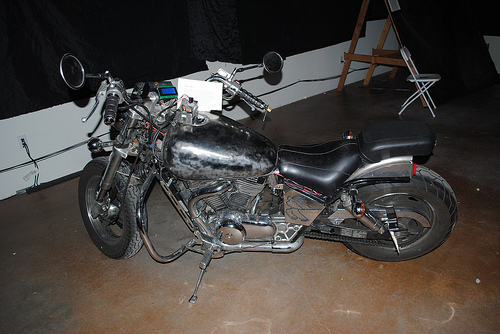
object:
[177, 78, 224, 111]
paper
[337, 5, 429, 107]
wooden support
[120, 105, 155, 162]
wires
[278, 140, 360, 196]
seat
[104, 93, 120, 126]
handle bar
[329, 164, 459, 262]
back wheel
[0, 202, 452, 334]
ground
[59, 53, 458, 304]
bike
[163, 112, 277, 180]
fuel tank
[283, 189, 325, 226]
brown panel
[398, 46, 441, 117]
chair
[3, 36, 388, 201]
panel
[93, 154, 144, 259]
dust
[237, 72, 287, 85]
shadow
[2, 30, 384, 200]
wood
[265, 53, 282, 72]
mirror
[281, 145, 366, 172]
black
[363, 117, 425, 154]
black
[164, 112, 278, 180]
cover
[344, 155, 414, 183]
tire panel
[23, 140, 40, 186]
cord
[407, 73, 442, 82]
seat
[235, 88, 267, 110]
handlebars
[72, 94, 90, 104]
shadow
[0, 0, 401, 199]
wall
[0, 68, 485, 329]
floor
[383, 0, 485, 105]
wood surface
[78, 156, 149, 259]
tire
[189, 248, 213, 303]
kick stand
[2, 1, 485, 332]
room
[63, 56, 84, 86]
mirror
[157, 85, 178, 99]
cellphone